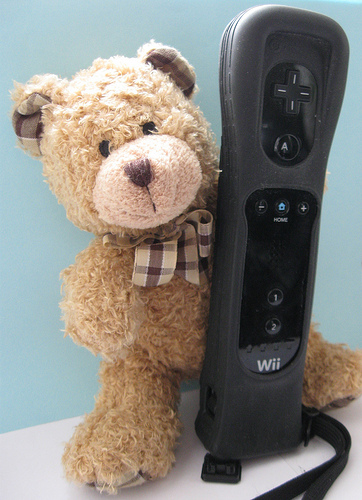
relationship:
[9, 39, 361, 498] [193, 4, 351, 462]
bear holding wii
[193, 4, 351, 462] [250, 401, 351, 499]
wii has strap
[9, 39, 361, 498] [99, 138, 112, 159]
bear has eye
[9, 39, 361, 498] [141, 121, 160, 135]
bear has eye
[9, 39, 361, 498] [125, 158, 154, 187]
bear has nose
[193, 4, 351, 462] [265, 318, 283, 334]
wii has button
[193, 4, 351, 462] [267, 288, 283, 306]
wii has button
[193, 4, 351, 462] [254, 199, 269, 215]
wii has button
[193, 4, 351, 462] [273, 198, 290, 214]
wii has button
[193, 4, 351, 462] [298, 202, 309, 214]
wii has button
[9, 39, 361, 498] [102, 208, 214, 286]
bear wearing scarf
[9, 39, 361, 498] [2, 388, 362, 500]
bear on top of object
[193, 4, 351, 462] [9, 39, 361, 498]
wii in front of bear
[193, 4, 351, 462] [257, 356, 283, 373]
wii has lettering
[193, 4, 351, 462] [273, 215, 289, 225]
wii has lettering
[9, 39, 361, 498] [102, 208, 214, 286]
bear has scarf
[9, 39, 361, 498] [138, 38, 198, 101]
bear has ear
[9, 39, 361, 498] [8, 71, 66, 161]
bear has ear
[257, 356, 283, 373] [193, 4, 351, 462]
lettering on front of wii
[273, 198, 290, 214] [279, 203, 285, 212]
button has icon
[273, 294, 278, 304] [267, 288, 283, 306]
number on button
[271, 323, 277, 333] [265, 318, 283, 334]
number on button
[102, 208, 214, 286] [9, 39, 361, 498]
scarf on bear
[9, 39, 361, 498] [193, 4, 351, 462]
bear next to wii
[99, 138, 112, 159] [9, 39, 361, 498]
eye on front of bear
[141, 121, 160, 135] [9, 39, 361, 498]
eye on front of bear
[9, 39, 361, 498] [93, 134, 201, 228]
bear has snout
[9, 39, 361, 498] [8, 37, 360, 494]
bear has fur